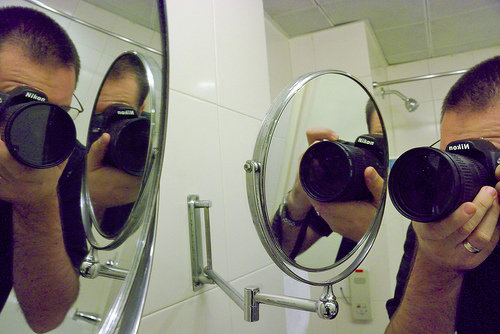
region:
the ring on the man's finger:
[463, 239, 480, 252]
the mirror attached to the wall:
[187, 68, 389, 321]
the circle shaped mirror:
[252, 69, 387, 271]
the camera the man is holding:
[387, 137, 498, 221]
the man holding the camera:
[383, 55, 498, 332]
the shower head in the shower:
[377, 87, 417, 112]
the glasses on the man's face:
[60, 93, 83, 120]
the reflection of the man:
[0, 5, 89, 332]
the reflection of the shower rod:
[25, 0, 163, 57]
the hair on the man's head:
[440, 54, 498, 115]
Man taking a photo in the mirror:
[2, 75, 82, 185]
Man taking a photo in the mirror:
[379, 126, 498, 223]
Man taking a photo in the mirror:
[91, 88, 161, 187]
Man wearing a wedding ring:
[461, 241, 481, 258]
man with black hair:
[440, 53, 498, 114]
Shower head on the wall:
[378, 73, 424, 123]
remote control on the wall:
[346, 263, 378, 323]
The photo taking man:
[384, 57, 499, 332]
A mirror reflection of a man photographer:
[244, 68, 389, 285]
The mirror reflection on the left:
[0, 0, 172, 333]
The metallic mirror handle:
[189, 198, 341, 319]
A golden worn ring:
[464, 238, 481, 255]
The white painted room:
[0, 0, 497, 333]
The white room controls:
[342, 268, 374, 326]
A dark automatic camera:
[389, 142, 499, 222]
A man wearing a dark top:
[386, 58, 498, 333]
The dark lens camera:
[388, 135, 498, 226]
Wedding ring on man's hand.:
[461, 241, 480, 255]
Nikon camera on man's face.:
[388, 138, 497, 224]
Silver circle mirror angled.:
[246, 71, 386, 280]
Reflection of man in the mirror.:
[273, 95, 391, 249]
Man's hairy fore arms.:
[12, 200, 71, 313]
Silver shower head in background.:
[379, 88, 421, 110]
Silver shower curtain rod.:
[373, 65, 455, 85]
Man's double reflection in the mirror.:
[1, 4, 154, 245]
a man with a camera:
[2, 81, 79, 171]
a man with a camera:
[80, 98, 157, 177]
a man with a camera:
[297, 131, 394, 208]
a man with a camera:
[383, 138, 499, 224]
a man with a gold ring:
[460, 234, 480, 256]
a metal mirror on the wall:
[185, 68, 390, 320]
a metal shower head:
[376, 87, 422, 114]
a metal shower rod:
[362, 69, 497, 90]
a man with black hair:
[436, 50, 496, 122]